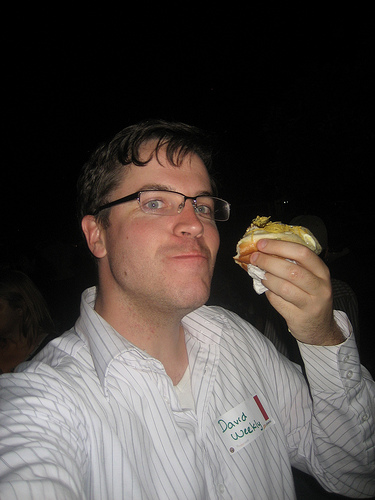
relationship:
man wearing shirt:
[0, 120, 375, 496] [0, 291, 373, 497]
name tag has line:
[211, 392, 275, 454] [251, 393, 268, 421]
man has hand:
[0, 120, 375, 496] [245, 243, 330, 300]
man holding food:
[0, 120, 375, 496] [226, 209, 313, 253]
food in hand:
[226, 209, 313, 253] [245, 243, 330, 300]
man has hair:
[0, 120, 375, 496] [88, 125, 151, 186]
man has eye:
[1, 93, 367, 496] [194, 202, 212, 216]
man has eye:
[1, 93, 367, 496] [142, 197, 165, 210]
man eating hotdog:
[0, 120, 375, 496] [223, 208, 327, 278]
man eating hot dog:
[0, 120, 375, 496] [230, 213, 324, 274]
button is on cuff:
[342, 353, 349, 362] [294, 311, 363, 392]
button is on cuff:
[346, 369, 353, 378] [294, 311, 363, 392]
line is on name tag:
[253, 393, 269, 420] [211, 392, 275, 454]